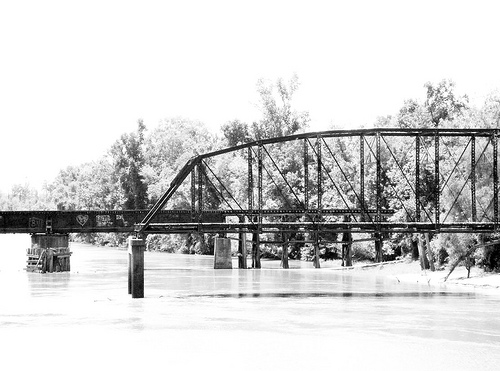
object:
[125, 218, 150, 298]
leg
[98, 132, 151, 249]
trees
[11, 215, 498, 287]
shore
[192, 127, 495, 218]
fence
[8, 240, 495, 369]
water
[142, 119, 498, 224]
trellis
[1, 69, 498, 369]
snow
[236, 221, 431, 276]
fence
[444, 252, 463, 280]
branch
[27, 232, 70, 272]
column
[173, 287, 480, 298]
reflection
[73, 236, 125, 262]
riverbank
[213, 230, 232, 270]
column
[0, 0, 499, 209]
sky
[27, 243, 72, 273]
wood pieces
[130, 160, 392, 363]
frozen lake/bridge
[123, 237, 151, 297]
column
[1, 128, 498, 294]
bridge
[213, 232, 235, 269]
stone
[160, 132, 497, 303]
bridge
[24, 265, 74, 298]
reflection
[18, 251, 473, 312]
riverbank